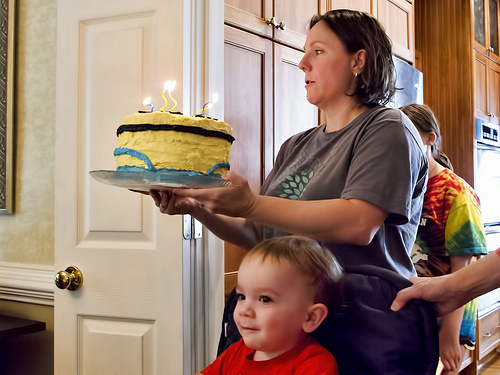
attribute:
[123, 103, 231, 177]
icing — yellow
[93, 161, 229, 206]
platter — glass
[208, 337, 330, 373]
shirt — red, tie dye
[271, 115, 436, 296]
shirt — gray, grey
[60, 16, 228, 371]
door — beige, white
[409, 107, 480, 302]
girl — young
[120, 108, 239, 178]
cake — yellow, birthday, kids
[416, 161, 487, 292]
shirt — tie dye, tie-dye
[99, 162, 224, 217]
plate — glass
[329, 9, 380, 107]
hair — brown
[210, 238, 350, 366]
boy — sitting, young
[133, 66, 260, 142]
candles — lit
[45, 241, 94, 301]
knob — gold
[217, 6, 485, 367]
people — celebrating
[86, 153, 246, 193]
pan — glass